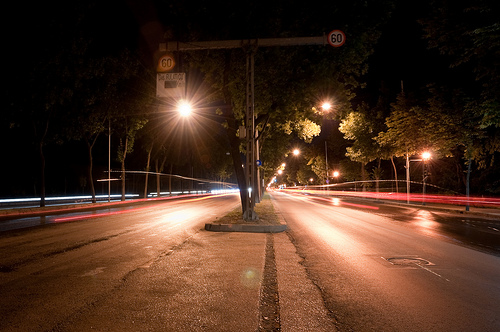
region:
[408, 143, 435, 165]
light on a pole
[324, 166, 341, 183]
light on a pole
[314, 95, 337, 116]
light on a pole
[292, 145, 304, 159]
light on a pole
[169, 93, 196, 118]
light on a pole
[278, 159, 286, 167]
light on a pole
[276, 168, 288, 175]
light on a pole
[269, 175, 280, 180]
light on a pole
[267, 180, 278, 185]
light on a pole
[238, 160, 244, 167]
light on a pole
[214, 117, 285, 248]
trees growing in the street median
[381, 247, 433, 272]
a round manhole cover in the road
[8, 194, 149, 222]
grey metal guard rail next to the street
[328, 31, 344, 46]
black numbers on a white sign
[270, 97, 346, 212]
street lights over the road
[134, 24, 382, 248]
a sign post in the median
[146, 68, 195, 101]
white sign hanging from a post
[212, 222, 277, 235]
grey concrete of the median curb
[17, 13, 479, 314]
Picture taken in the evening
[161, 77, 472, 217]
Several streetlights are on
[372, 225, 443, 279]
Man hole cover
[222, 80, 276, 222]
Trees growing on the median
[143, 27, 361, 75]
Two signs that say 60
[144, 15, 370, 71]
60 is surrounded by a red circle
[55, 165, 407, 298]
There are no vehicles on the road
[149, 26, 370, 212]
60 signs connected to metal pole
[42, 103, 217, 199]
Trees growing along the side of the street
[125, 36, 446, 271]
Lights on the road.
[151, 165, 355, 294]
Grass on the cement.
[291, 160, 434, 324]
Light on the road.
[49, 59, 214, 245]
Trees by the road.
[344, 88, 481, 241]
Trunks of the trees.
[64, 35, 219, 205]
Trees against the roads.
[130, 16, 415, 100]
Sign over the road.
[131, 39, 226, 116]
numbers on the sign.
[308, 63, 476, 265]
Bright lights on the poles.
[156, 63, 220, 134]
light on the top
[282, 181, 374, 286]
a white light on road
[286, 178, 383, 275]
light falling in road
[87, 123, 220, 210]
a fence near water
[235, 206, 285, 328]
a black mark in road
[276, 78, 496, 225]
white light in road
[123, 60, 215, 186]
a electric pole near water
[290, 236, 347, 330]
small mark in the road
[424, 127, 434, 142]
green leaves on the tree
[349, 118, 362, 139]
green leaves on the tree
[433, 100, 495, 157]
green leaves on the tree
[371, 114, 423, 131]
green leaves on the tree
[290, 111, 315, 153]
green leaves on the tree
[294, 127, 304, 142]
green leaves on the tree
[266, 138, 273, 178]
green leaves on the tree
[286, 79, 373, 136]
light above the street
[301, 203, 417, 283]
street under the trees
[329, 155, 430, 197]
branches of the trees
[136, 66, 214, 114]
sign above the street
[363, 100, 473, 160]
leaves on the tree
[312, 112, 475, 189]
tres next to the road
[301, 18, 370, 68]
number on round sign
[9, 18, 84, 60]
black sky above land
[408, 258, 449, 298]
line on the street